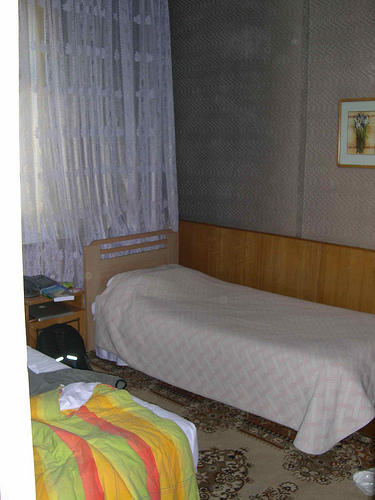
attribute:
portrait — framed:
[333, 96, 370, 173]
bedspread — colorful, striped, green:
[30, 382, 199, 498]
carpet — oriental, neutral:
[79, 354, 371, 499]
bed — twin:
[81, 225, 374, 450]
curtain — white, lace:
[21, 2, 181, 291]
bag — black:
[33, 323, 93, 371]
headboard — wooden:
[80, 228, 181, 357]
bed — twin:
[26, 338, 199, 499]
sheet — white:
[32, 344, 201, 473]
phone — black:
[23, 276, 60, 295]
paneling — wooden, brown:
[175, 217, 372, 316]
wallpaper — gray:
[166, 0, 373, 250]